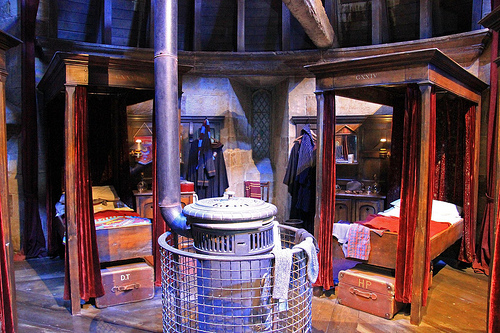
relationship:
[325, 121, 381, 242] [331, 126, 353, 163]
vanity station with mirror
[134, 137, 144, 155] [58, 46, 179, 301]
candle lamp by canopy post bed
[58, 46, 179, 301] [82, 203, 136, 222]
canopy post bed has blanket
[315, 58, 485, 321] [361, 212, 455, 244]
canopy post bed has blanket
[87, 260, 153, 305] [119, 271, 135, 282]
bed drawer with d.t.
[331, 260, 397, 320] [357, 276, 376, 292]
bed drawer with h.p.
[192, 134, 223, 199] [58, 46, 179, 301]
robe hanging by canopy post bed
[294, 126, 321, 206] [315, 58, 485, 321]
bathrobe hanging by canopy post bed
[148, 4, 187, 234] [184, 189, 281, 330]
heat pipe for gas heater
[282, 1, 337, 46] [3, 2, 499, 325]
beam in bedroom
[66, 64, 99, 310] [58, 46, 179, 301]
column of canopy post bed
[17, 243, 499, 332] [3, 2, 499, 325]
floor in bedroom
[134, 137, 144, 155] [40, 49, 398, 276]
candle lamp mounted to wall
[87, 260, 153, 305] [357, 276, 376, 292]
bed drawer for h.p.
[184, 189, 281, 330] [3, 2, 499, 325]
gas heater in bedroom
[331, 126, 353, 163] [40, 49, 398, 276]
mirror hung on wall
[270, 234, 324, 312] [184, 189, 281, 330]
socks drying near gas heater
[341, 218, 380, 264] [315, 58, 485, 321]
pajamas on canopy post bed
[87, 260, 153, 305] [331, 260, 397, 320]
bed drawer and bed drawer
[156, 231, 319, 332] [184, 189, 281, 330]
basket around gas heater